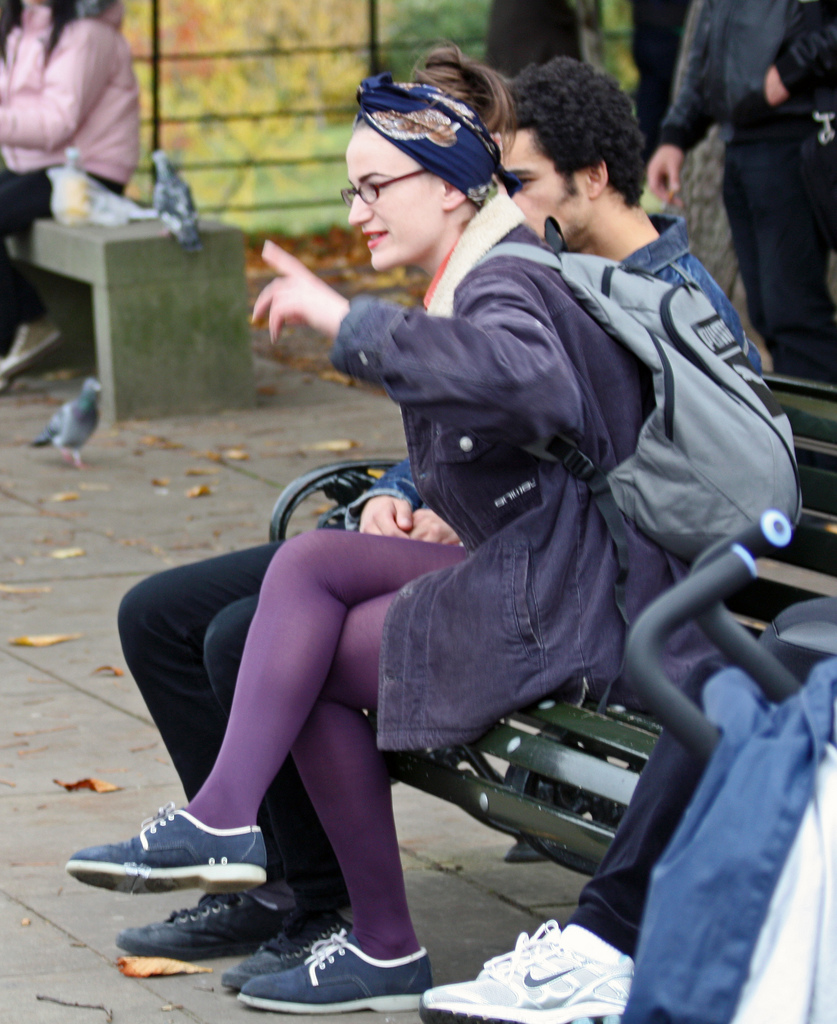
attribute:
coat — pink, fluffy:
[0, 0, 142, 180]